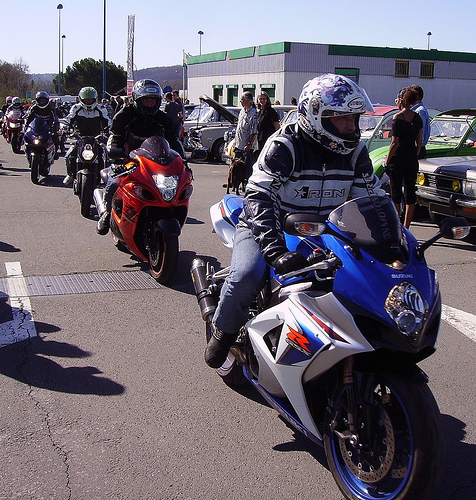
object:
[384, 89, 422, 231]
woman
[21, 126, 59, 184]
motorcycle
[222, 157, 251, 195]
dog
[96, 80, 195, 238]
person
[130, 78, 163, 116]
helmet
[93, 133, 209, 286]
motorcycle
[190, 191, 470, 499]
motorcylcles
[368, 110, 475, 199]
car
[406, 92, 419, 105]
ponytail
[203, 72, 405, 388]
person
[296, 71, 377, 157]
helmet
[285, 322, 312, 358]
lettering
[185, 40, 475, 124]
building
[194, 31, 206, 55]
street lights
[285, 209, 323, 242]
side view mirror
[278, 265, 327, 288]
brake handle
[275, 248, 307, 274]
glove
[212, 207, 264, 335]
leg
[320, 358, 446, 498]
tire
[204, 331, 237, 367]
boot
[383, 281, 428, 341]
headlight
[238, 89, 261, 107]
head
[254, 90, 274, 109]
head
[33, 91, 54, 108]
head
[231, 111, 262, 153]
shirt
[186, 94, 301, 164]
car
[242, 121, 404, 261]
jacket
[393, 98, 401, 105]
sunglasses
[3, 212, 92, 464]
street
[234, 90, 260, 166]
person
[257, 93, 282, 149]
person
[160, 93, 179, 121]
person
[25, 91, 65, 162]
person